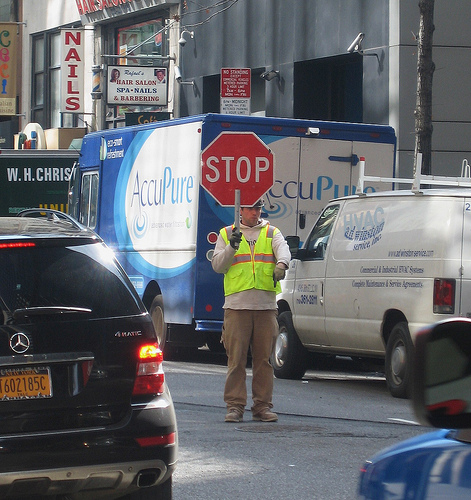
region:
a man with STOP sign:
[185, 114, 308, 410]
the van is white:
[270, 183, 437, 423]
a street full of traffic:
[9, 54, 459, 478]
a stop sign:
[192, 139, 272, 229]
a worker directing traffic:
[192, 137, 343, 406]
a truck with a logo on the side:
[118, 167, 206, 266]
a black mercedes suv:
[3, 222, 238, 481]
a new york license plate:
[5, 364, 67, 399]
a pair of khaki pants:
[215, 301, 295, 441]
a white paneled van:
[317, 185, 421, 388]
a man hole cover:
[235, 417, 326, 440]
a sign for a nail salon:
[56, 25, 107, 119]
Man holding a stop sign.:
[209, 195, 290, 425]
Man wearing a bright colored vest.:
[211, 193, 289, 427]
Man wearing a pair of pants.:
[211, 193, 295, 425]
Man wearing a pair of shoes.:
[208, 191, 292, 427]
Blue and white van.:
[59, 109, 400, 358]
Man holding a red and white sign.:
[209, 195, 289, 424]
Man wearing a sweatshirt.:
[211, 193, 292, 426]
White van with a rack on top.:
[271, 153, 469, 399]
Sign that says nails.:
[56, 24, 86, 115]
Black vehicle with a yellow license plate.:
[2, 203, 176, 498]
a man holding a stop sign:
[200, 120, 290, 428]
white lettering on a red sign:
[205, 150, 270, 191]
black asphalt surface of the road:
[228, 435, 323, 487]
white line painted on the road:
[387, 411, 415, 432]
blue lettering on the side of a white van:
[350, 244, 432, 298]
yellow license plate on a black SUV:
[0, 364, 63, 409]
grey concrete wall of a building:
[212, 12, 316, 54]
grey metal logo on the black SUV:
[7, 331, 35, 357]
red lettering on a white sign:
[60, 32, 83, 111]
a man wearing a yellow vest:
[214, 193, 287, 417]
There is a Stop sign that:
[223, 127, 260, 184]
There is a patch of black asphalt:
[249, 457, 263, 488]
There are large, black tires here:
[394, 319, 410, 353]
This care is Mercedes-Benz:
[11, 325, 37, 363]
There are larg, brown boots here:
[223, 397, 241, 444]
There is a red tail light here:
[437, 279, 457, 318]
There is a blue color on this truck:
[174, 276, 194, 301]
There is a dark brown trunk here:
[423, 91, 455, 281]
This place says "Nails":
[58, 75, 99, 128]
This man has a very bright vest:
[239, 253, 267, 305]